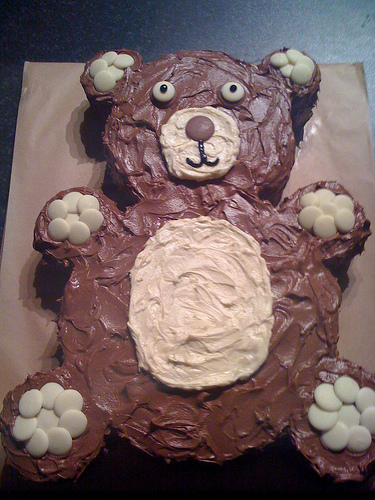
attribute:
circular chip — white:
[150, 80, 177, 103]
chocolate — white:
[293, 176, 355, 251]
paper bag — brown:
[3, 58, 374, 400]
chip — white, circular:
[54, 407, 90, 440]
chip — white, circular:
[50, 384, 87, 423]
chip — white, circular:
[34, 377, 65, 412]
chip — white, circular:
[15, 385, 46, 418]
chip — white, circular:
[10, 412, 42, 444]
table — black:
[1, 0, 374, 499]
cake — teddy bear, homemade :
[0, 46, 373, 485]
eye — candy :
[221, 82, 244, 102]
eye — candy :
[151, 79, 175, 102]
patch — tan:
[122, 217, 281, 389]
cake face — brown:
[91, 48, 299, 189]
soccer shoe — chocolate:
[183, 116, 217, 143]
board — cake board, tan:
[1, 61, 373, 412]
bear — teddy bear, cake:
[0, 47, 373, 483]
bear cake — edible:
[2, 45, 371, 482]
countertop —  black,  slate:
[2, 4, 371, 59]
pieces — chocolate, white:
[53, 198, 98, 241]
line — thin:
[195, 144, 203, 161]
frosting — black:
[182, 141, 204, 170]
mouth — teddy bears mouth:
[174, 140, 223, 166]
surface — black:
[241, 12, 306, 41]